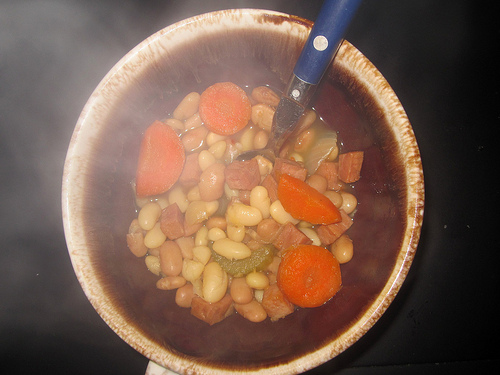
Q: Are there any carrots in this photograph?
A: Yes, there is a carrot.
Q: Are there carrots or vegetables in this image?
A: Yes, there is a carrot.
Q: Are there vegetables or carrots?
A: Yes, there is a carrot.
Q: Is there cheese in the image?
A: No, there is no cheese.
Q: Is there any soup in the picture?
A: Yes, there is soup.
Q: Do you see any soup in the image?
A: Yes, there is soup.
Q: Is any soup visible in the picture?
A: Yes, there is soup.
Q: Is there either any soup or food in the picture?
A: Yes, there is soup.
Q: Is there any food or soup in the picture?
A: Yes, there is soup.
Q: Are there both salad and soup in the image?
A: No, there is soup but no salad.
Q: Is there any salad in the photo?
A: No, there is no salad.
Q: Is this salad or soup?
A: This is soup.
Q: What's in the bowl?
A: The soup is in the bowl.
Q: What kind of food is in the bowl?
A: The food is soup.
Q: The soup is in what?
A: The soup is in the bowl.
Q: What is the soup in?
A: The soup is in the bowl.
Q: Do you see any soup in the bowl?
A: Yes, there is soup in the bowl.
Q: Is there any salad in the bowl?
A: No, there is soup in the bowl.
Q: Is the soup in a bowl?
A: Yes, the soup is in a bowl.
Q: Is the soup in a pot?
A: No, the soup is in a bowl.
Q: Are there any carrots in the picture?
A: Yes, there is a carrot.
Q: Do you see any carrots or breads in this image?
A: Yes, there is a carrot.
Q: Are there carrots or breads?
A: Yes, there is a carrot.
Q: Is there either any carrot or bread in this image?
A: Yes, there is a carrot.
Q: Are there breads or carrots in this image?
A: Yes, there is a carrot.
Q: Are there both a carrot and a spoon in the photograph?
A: Yes, there are both a carrot and a spoon.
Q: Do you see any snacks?
A: No, there are no snacks.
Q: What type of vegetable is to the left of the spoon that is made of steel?
A: The vegetable is a carrot.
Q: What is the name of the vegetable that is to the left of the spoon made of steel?
A: The vegetable is a carrot.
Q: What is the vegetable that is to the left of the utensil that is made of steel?
A: The vegetable is a carrot.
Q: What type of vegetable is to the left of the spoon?
A: The vegetable is a carrot.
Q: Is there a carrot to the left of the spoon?
A: Yes, there is a carrot to the left of the spoon.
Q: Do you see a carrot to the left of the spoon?
A: Yes, there is a carrot to the left of the spoon.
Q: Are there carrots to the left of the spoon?
A: Yes, there is a carrot to the left of the spoon.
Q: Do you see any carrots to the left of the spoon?
A: Yes, there is a carrot to the left of the spoon.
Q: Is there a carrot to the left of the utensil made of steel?
A: Yes, there is a carrot to the left of the spoon.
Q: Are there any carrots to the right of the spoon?
A: No, the carrot is to the left of the spoon.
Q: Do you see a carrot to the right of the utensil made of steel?
A: No, the carrot is to the left of the spoon.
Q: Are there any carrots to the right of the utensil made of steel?
A: No, the carrot is to the left of the spoon.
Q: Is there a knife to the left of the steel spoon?
A: No, there is a carrot to the left of the spoon.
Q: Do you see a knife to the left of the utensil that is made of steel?
A: No, there is a carrot to the left of the spoon.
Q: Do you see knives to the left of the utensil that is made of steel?
A: No, there is a carrot to the left of the spoon.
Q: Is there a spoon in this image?
A: Yes, there is a spoon.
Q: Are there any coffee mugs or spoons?
A: Yes, there is a spoon.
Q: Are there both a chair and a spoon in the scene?
A: No, there is a spoon but no chairs.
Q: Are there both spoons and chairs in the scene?
A: No, there is a spoon but no chairs.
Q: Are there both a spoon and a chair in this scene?
A: No, there is a spoon but no chairs.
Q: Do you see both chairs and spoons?
A: No, there is a spoon but no chairs.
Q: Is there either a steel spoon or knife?
A: Yes, there is a steel spoon.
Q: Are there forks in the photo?
A: No, there are no forks.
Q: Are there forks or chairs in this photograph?
A: No, there are no forks or chairs.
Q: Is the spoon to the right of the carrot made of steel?
A: Yes, the spoon is made of steel.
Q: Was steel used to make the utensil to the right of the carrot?
A: Yes, the spoon is made of steel.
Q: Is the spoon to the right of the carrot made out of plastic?
A: No, the spoon is made of steel.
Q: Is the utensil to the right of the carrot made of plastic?
A: No, the spoon is made of steel.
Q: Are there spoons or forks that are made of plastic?
A: No, there is a spoon but it is made of steel.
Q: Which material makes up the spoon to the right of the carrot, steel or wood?
A: The spoon is made of steel.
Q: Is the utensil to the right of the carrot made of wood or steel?
A: The spoon is made of steel.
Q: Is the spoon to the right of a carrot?
A: Yes, the spoon is to the right of a carrot.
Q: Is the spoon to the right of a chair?
A: No, the spoon is to the right of a carrot.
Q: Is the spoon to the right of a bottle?
A: No, the spoon is to the right of a carrot.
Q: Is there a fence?
A: No, there are no fences.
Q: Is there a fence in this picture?
A: No, there are no fences.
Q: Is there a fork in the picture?
A: No, there are no forks.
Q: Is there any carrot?
A: Yes, there is a carrot.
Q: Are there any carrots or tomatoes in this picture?
A: Yes, there is a carrot.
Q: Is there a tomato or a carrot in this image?
A: Yes, there is a carrot.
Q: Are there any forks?
A: No, there are no forks.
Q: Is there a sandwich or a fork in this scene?
A: No, there are no forks or sandwiches.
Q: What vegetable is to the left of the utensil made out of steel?
A: The vegetable is a carrot.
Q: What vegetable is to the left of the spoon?
A: The vegetable is a carrot.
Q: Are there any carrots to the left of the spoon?
A: Yes, there is a carrot to the left of the spoon.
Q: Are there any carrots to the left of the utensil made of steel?
A: Yes, there is a carrot to the left of the spoon.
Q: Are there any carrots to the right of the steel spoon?
A: No, the carrot is to the left of the spoon.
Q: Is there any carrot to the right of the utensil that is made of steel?
A: No, the carrot is to the left of the spoon.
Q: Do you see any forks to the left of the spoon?
A: No, there is a carrot to the left of the spoon.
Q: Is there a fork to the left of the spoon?
A: No, there is a carrot to the left of the spoon.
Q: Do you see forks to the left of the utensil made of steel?
A: No, there is a carrot to the left of the spoon.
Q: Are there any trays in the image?
A: No, there are no trays.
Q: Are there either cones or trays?
A: No, there are no trays or cones.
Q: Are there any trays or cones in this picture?
A: No, there are no trays or cones.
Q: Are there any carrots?
A: Yes, there is a carrot.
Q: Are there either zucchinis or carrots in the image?
A: Yes, there is a carrot.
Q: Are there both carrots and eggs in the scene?
A: No, there is a carrot but no eggs.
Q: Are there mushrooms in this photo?
A: No, there are no mushrooms.